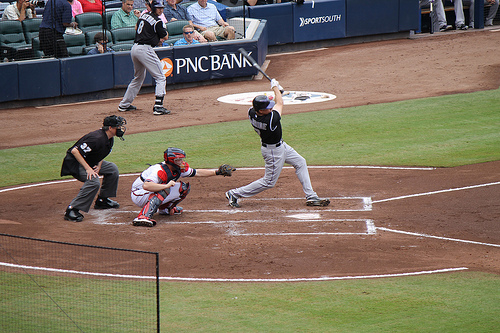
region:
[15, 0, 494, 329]
Baseball is the game being played.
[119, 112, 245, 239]
Catcher wearing a white uniform.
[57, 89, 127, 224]
Umpire wearing a black shirt.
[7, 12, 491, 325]
Photo taken during the day.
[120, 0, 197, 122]
Left handed on-deck batter.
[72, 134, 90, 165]
37 on the umpire's shirt.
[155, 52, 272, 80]
PNC BANK ad behind the on-deck batter.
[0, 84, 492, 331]
Grass is green.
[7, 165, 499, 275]
The dirt is brown.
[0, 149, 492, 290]
Lines on the field are white.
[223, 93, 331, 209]
Baseball players swinging bat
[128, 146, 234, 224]
baseball catcher in a squat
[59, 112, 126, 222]
baseball umpire in dark clothing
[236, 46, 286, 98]
black baseball bat being swung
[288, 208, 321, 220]
home plate on a baseball field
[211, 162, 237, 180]
brown catcher's mitt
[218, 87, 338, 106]
on deck circle at baseball field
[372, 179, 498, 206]
third base line on baseball field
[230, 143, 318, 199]
gray baseball pants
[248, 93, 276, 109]
black baseball helmet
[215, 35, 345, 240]
baseball player with bat above head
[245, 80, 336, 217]
athlete with a twisted foot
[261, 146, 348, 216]
foot inside two white lines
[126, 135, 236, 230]
catcher with arm extended in front of him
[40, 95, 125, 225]
umpire crouched down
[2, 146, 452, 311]
rectangles within an oval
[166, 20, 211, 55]
fan in sunglasses in first row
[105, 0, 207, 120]
player standing sideways near fans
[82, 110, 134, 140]
protective equipment over head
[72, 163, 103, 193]
hand resting on knee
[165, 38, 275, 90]
Pnc bank written on wall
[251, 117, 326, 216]
Man wearing gray pants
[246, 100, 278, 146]
Man wearing black shirt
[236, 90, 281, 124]
Man wearing black hat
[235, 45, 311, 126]
Baseball bat is black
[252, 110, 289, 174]
Man wearing black belt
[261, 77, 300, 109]
Man wearing white glove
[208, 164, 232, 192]
Catcher has black mitt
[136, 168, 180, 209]
Man wearing white uniform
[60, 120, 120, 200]
Umpire has on black shirt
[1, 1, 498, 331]
A professional baseball game.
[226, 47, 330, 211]
The batter in position to strike the ball.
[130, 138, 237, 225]
The catcher in a squatted position.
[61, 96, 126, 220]
The referee watching intensely.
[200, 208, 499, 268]
The brown turf on the ground.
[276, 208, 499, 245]
The white lines on the turf.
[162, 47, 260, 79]
The PNC BANK sign.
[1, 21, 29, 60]
The comfortable cobalt blue chairs.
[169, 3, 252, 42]
The audience watching the game.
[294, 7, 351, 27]
The Sport South sign.